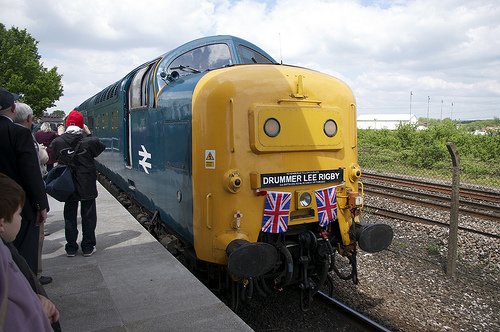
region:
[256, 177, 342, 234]
British flags on front of train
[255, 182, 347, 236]
English flags on front of train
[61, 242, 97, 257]
Man is wearing shoes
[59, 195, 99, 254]
Man is wearing pants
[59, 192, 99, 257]
Man is wearing jeans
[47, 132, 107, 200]
Man is wearing a jacket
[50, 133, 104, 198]
Man is wearing a black jacket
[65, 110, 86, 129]
Man is wearing a hat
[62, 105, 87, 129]
Man is wearing a red hat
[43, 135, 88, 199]
Man is carrying a bag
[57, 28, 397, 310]
Blue and yellow train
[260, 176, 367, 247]
Two england flags on front of train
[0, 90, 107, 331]
Group of people waiting for train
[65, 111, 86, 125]
Person wearing red hat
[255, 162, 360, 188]
Black and white name sign on front of train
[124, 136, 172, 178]
White logo on side of train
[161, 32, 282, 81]
Two pairs of windows on front of train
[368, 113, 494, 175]
Small green bushes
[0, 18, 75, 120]
Part of tree on the side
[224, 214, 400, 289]
Pair of two black speakers on front of train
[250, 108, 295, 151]
light on front of train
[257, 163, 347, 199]
words on front of train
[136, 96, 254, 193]
yellow and blue train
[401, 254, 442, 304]
rocks next to train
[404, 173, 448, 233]
tracks next to train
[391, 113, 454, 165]
trees in the distance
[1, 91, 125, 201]
people next to train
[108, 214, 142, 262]
shadow on the ground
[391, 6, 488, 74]
clouds in the sky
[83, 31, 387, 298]
a yellow and blue train engine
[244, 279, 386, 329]
a set of train tracks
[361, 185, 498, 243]
a set of train tracks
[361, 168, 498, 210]
a set of train tracks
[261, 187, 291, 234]
a red white and blue British flag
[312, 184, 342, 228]
a red white and blue British flag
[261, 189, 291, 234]
a small Union Jack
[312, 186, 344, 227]
a small Union Jack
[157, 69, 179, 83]
a blue train horn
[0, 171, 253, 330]
a train boarding platform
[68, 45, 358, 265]
a yellow and blue train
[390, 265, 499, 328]
brown and white gravels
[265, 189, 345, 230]
a flag on the train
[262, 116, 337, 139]
lights on a train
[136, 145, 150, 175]
a white symbol on a train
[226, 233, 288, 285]
bumpers on a train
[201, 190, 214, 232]
a yellow handle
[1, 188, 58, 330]
a child watching a train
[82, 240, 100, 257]
blue and white tennis shoes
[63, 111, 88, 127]
a red knitted cap